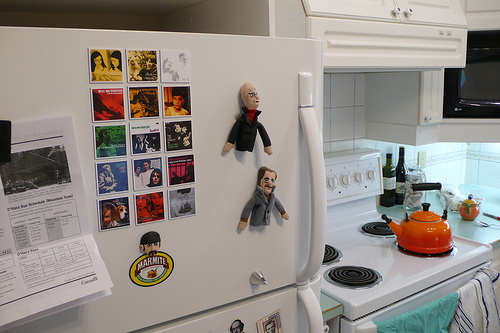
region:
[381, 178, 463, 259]
Orange teakettle on the stovetop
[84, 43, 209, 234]
Set of twelve refrigerator magnets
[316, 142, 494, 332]
White stove/oven combination with four burners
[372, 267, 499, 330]
Two dish towels, one green and one striped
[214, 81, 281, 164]
Refrigerator magnet of a man in black jacket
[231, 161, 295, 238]
Refrigerator magnet of a man with a gray jacket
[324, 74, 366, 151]
White square tile above the stove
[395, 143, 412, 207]
Black bottle of wine with a white label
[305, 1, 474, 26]
Kitchen cabinet above the stove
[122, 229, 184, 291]
Refrigerator magnet advertising Marmite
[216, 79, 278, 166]
Man in suit as frig magnet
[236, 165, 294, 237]
Man in suit as frig magnet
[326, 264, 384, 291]
Burner on white stove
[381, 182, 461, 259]
Orange tea kettle on stove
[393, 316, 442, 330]
Part of blue tea towel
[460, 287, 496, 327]
Part of striped tea towel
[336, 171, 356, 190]
Control knob for stove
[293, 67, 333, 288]
Freezer door handle for white frig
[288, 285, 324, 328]
Part of handle for white frig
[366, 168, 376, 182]
Control knob for white stove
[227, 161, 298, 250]
refrigerator magnet of a person in a coat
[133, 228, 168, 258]
cartoon refrigerator magnet of one of the members of the Beatles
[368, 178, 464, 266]
orange teapot sitting on a stove burner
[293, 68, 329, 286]
white handle on a freezer door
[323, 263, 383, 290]
black metal stove top burner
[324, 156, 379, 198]
row of white stove nobs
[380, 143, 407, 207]
bottles of oil in the kitchen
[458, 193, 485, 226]
small orange ceramic sugar bowl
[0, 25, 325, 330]
refrigerator and freezer with magnets on it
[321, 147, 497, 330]
white stove with a teapot on it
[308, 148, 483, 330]
White electric stove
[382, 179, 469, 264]
Orange kettle on the stove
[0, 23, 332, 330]
Freezer section of the refrigerator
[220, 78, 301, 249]
Fridge magnets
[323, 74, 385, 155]
White tiles over the stove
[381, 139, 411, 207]
Two green glass bottles on the countertop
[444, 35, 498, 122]
Black microwave oven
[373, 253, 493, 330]
Kitchen towels hung on the oven handle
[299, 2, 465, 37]
White kitchen cabinet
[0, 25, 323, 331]
the white refrigerator next to the stove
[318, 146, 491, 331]
the stove next to the refrigerator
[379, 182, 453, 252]
the orange tea kettle on the stove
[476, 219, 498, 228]
the spoon on the counter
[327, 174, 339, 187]
the knob on the stove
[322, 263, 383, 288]
the burner on the stove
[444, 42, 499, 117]
the black microwave on the shelf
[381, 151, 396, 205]
the bottle on the counter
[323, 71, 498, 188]
the tile on the walls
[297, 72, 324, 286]
the handle on the freezer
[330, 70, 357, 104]
a tile in a wall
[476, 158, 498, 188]
a tile in a wall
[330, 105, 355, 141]
a tile in a wall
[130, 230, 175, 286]
A magnet on a refrigerator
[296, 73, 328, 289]
A handle on a freezer door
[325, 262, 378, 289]
A burner on a stove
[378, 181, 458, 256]
A kettle on the stove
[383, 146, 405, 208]
Bottles in the kitchen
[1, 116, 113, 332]
Paper hanging on a freezer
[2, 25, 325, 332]
A refrigerator in the kitchen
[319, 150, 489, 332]
A stove in the kitchen